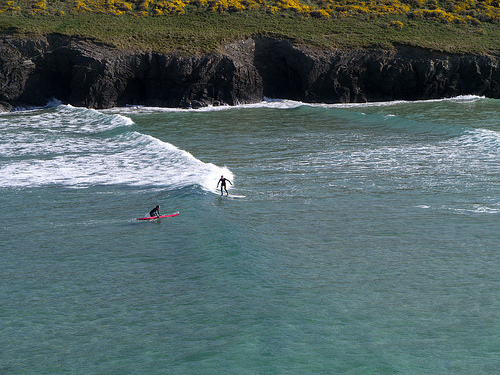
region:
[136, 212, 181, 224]
long red surf board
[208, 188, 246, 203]
long white surf board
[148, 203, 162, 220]
person wearing wet suit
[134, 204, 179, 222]
person kneeling on surf board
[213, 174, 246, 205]
person standing on surf board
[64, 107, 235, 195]
wave formed in ocean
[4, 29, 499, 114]
cliff next to ocean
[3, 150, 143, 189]
white foam in ocean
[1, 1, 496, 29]
yellow flowers on ground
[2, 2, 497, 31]
wild flowers on ground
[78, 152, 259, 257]
people in the water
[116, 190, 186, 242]
person on a board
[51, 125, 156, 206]
white water in the photo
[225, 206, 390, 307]
still water in the photo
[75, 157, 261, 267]
two people in water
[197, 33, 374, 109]
rocks behind the men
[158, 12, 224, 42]
grass on the ground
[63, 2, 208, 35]
yellow bushes in the distance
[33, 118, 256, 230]
two surfers in the ocean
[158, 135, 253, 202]
one surfer is riding a wave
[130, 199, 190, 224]
one surfer is paddling on his board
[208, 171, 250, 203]
this surfboard dude has a white board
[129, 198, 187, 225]
this surfboard dude has a pink board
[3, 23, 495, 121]
cliffs at the water's edge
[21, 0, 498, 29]
yellow flowering vegetation above the cliffs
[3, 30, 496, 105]
the cliffs are dark stone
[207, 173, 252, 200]
surfer dude is wearing a wetsuit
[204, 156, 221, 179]
white wave in water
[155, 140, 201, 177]
white wave in water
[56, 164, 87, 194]
white wave in water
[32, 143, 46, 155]
white wave in water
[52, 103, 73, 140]
white wave in water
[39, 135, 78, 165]
white wave in water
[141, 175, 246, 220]
Two surfers in the water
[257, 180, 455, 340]
A large body of water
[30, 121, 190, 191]
Waves in the water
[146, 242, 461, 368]
Blue and green water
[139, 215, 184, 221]
A surfer's pink surfboard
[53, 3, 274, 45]
Green and yellow vegetation in the background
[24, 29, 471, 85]
Raised up land in the distance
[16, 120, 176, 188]
Waves in the ocean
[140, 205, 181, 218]
A surfer on a surfboard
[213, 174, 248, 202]
A surfer riding the waves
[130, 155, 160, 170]
the wave is white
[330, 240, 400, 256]
the ocean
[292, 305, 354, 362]
the ocean water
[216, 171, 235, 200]
a person surfing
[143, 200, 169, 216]
a person in the water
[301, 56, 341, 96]
a rock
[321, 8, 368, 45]
the grass is low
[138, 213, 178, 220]
a surfboard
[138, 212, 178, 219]
the surfboard is red